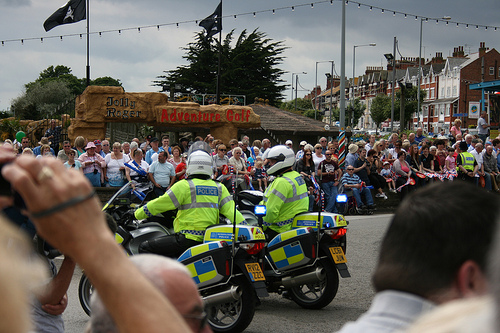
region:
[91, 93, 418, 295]
this is a parade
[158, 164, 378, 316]
these are motorcyle cops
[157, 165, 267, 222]
the jackets are bright green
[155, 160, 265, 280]
the jackets are for safety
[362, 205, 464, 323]
the hair is short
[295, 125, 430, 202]
this is a big group of people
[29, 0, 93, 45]
this is a flag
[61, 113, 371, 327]
2 people on motorcycles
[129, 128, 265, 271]
this is a police officer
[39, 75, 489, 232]
spectators lining the street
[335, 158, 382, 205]
a man sitting down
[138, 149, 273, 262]
officer wearing green jacket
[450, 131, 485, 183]
man facing the crowd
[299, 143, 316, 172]
this is a woman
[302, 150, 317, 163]
woman wearing dark sunglasses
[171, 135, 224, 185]
officer wearing white helmet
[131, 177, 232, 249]
man has green coat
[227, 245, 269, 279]
black and yellow license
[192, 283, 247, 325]
black wheel on bike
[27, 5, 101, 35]
black and white flag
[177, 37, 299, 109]
green pines in distance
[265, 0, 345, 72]
grey and white sky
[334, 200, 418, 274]
bikes on grey concrete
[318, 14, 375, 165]
grey pole near people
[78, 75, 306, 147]
red and brown mini golf sign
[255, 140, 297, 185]
Head of a person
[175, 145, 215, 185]
Head of a person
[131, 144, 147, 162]
Head of a person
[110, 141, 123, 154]
Head of a person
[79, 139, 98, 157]
Head of a person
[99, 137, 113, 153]
Head of a person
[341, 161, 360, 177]
Head of a person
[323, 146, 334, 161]
Head of a person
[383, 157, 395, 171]
Head of a person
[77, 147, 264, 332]
police officer on a motorcycle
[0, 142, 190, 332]
person with a strap around hand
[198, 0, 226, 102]
black flag on black pole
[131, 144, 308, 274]
two motorcyclist wearing light green jackets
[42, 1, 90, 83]
black flag on pole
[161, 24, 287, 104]
big tree behind sotre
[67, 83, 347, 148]
store with red sign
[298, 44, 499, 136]
houses in the background in right side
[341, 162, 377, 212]
person sitting on blue and white lines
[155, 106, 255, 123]
red letters on sign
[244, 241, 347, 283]
yellow license plates of motorcycle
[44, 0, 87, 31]
The flag on the left is black in color.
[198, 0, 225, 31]
The flag on the right is black in color.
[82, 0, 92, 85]
The left flag pole is made from metal.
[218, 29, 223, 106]
The right flag pole is made from metal.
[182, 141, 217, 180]
The police man on the left has a white helmet.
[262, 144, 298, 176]
The police man on the right has a white helmet.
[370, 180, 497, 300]
The man in the forefront on the right has short hair.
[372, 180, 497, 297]
The man on the right in the forefront has brown hair.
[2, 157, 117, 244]
The person in the forefront is wearing a gold ring.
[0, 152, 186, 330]
The person in the forefront on the left is holding a camera.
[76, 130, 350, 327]
two police officers on motorcycles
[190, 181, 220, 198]
square blue patch with the word "POLICE" in a grey font and uppercase letters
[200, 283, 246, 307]
long cylindrical silver tailpipe on motorcycle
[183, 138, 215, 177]
white helmet with transparent plastic visor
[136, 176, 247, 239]
neon lime colored hazard jacket